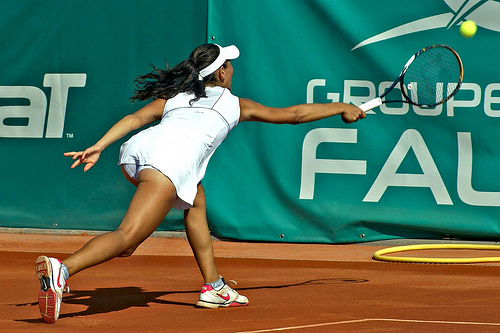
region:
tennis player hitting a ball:
[10, 7, 497, 332]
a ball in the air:
[448, 15, 488, 46]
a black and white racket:
[339, 38, 465, 128]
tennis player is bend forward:
[20, 22, 379, 325]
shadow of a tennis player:
[18, 210, 280, 331]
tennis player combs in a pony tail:
[111, 17, 277, 130]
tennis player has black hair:
[114, 24, 256, 130]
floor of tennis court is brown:
[16, 227, 499, 332]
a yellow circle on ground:
[369, 232, 499, 270]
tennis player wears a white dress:
[67, 17, 268, 208]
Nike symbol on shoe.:
[212, 287, 236, 302]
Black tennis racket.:
[343, 36, 473, 126]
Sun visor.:
[194, 34, 251, 80]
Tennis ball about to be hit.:
[444, 14, 484, 47]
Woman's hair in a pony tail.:
[129, 31, 249, 110]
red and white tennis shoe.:
[29, 246, 73, 324]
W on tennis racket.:
[414, 51, 455, 98]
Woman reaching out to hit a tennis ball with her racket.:
[19, 22, 374, 325]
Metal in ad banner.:
[269, 226, 291, 243]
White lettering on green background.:
[1, 23, 102, 180]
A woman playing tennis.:
[116, 28, 440, 162]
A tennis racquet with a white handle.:
[315, 35, 480, 127]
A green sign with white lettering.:
[225, 64, 435, 204]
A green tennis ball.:
[434, 20, 489, 46]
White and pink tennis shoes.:
[23, 252, 280, 317]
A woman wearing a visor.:
[148, 37, 252, 95]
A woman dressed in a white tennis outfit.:
[152, 51, 255, 221]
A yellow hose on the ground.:
[364, 217, 499, 282]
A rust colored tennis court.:
[270, 253, 412, 311]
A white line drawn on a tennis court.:
[286, 295, 458, 331]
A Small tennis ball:
[456, 19, 481, 36]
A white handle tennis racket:
[344, 45, 471, 127]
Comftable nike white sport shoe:
[191, 275, 264, 308]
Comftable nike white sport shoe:
[27, 257, 76, 316]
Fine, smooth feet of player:
[73, 175, 155, 267]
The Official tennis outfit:
[33, 37, 253, 319]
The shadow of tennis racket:
[276, 276, 371, 297]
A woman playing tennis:
[25, 20, 480, 313]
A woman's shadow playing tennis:
[77, 286, 184, 317]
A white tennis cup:
[197, 37, 242, 75]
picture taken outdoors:
[64, 56, 491, 244]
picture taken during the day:
[67, 58, 452, 307]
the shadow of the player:
[78, 261, 204, 323]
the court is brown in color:
[245, 251, 390, 276]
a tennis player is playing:
[91, 37, 499, 207]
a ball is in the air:
[410, 31, 480, 95]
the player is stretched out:
[71, 35, 352, 323]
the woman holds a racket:
[142, 71, 492, 197]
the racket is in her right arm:
[251, 63, 479, 120]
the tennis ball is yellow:
[454, 11, 494, 69]